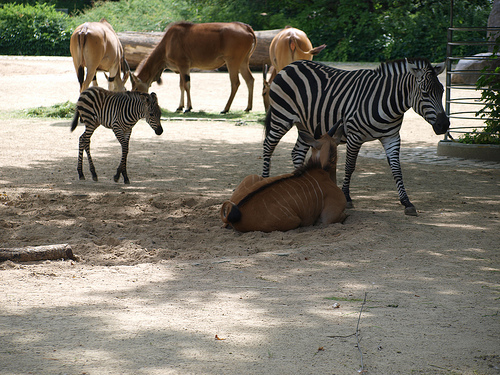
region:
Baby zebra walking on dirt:
[74, 84, 172, 180]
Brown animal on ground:
[224, 164, 350, 230]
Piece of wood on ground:
[0, 243, 103, 262]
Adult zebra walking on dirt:
[264, 55, 461, 222]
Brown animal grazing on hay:
[127, 18, 258, 113]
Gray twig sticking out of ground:
[337, 283, 378, 359]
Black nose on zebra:
[431, 115, 451, 131]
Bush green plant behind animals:
[2, 1, 84, 54]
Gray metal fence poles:
[442, 2, 498, 174]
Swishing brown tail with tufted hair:
[295, 36, 325, 58]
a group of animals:
[47, 9, 454, 259]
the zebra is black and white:
[248, 38, 453, 215]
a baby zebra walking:
[64, 80, 172, 189]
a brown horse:
[114, 8, 281, 129]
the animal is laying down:
[214, 132, 371, 252]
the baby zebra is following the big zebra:
[49, 41, 466, 238]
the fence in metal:
[434, 1, 498, 171]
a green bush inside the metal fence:
[433, 3, 498, 170]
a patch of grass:
[14, 87, 303, 134]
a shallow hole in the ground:
[1, 178, 371, 280]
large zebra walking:
[248, 42, 459, 216]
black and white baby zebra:
[40, 89, 170, 189]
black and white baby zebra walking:
[58, 89, 162, 196]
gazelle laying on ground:
[224, 153, 365, 247]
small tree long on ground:
[0, 235, 78, 289]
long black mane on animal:
[231, 163, 326, 213]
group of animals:
[47, 8, 471, 289]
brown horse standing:
[137, 22, 265, 114]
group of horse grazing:
[48, 19, 330, 100]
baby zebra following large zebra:
[71, 52, 462, 193]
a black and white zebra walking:
[70, 83, 165, 183]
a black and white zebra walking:
[257, 59, 448, 220]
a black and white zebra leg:
[72, 123, 94, 177]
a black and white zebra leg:
[80, 118, 103, 178]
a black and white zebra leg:
[100, 123, 130, 186]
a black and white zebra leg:
[121, 123, 135, 183]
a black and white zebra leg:
[258, 92, 288, 182]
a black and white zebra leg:
[291, 113, 311, 168]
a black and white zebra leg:
[343, 110, 358, 205]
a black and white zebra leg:
[383, 119, 415, 214]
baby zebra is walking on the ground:
[70, 83, 168, 185]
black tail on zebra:
[70, 102, 84, 132]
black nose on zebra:
[155, 126, 162, 134]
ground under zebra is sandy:
[3, 53, 498, 373]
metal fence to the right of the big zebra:
[441, 28, 498, 143]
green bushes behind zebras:
[1, 1, 498, 56]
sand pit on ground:
[1, 191, 366, 261]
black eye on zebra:
[421, 90, 431, 97]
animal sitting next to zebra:
[220, 118, 354, 233]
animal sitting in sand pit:
[213, 118, 353, 233]